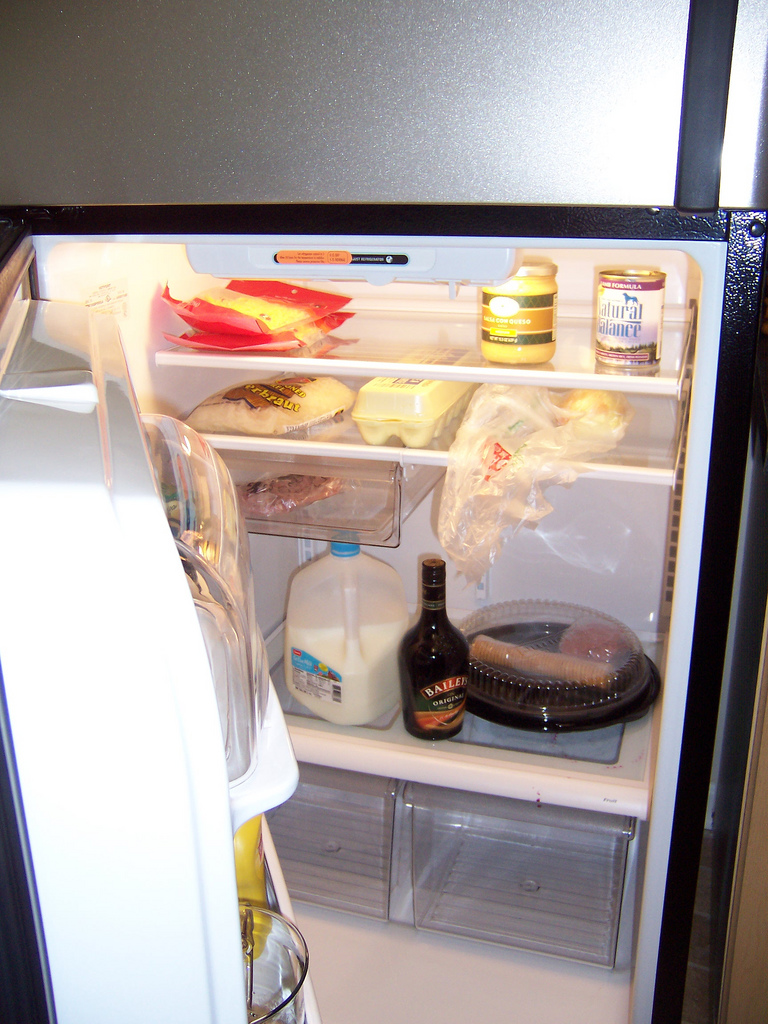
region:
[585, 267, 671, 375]
Can in the refrigerator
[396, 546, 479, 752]
bottle of Bailey in the refrigerator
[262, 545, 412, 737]
gallon of milk in the refrigerator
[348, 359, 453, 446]
egg carton in the refrigerator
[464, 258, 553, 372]
jar in the refrigerator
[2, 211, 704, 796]
refrigerator door is opened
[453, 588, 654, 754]
tray of food in the refrigerator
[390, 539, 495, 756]
Bottle in the refrigerator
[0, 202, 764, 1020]
A refrigerator with an open door.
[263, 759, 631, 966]
Two empty crisper drawers.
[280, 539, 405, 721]
A bottle of milk with a blue top.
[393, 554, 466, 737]
A brown bottle of Baileys.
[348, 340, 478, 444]
A carton of eggs on the second shelf.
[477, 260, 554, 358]
A yellow glass jar of cheese on top shelf.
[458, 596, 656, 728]
A container of food with a plastic lid.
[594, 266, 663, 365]
A can of pet food on the top shelf.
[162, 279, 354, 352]
Two red plastic bags on the top shelf.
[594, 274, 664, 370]
Can of dog food on shelf.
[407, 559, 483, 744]
Bottle of baileys in fridge.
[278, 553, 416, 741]
Gallon of milk on shelf.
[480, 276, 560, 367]
Container of orange food on top shelf.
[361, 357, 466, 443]
Carton of eggs on shelf.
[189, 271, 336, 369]
Two bags of cheese on shelf.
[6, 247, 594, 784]
Fridge door is open.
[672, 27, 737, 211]
Black handle on freezer door.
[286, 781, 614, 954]
Drawers on bottom are clear.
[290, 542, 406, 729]
A gallon of milk in the fridge.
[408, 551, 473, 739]
A black bottle sitting next to the milk.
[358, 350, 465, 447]
A carton of eggs in the refrigerator.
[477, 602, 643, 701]
A clear lid over the food.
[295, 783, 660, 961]
Two clear drawers in the refrigerator.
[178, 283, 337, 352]
Two bag of cheese on the top shelf.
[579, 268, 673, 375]
A can sitting on the top shelf.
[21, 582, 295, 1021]
The door of the refrigerator is open.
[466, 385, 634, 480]
A plastic bag on the shelf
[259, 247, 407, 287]
A label on the top shelf.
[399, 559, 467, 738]
black bottle of Baileys with black cap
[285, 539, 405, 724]
clear jug of milk with blue lid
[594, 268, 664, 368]
purple and white can of dog food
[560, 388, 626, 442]
yellow onion wrapped in clear bag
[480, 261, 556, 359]
clear jar of queso on fridge shelf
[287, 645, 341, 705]
blue and white label on plastic jug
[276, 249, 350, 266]
orange sticker on white fridge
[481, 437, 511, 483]
red logo on clear plastic bag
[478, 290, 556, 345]
green and orange label on glass jar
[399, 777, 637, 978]
empty clear plastic bin in fridge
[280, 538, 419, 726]
gallon of milk in the refrigerator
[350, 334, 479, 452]
carton of eggs in the refrigerator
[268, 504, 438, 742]
A jug of milk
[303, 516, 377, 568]
Blue cap of a milk jug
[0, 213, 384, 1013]
An open fridge door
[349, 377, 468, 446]
a carton of eggs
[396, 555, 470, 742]
a bottle of alcohol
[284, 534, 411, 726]
a gallon of milk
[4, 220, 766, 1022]
an open refrigerator door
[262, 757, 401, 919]
a clear refrigerator drawer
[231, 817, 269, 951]
a bottle of mustard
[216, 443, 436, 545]
a clear refrigerator drawer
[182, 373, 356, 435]
a bag of rice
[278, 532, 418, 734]
food in a refrigerator